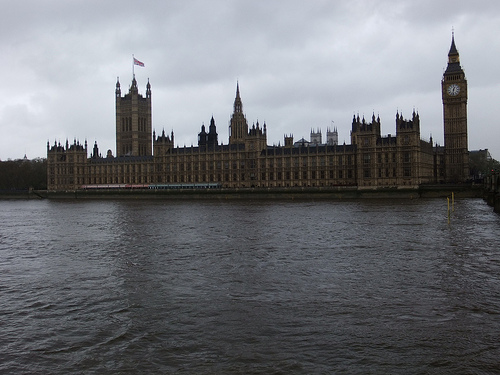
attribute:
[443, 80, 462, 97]
clock —  round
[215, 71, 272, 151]
tower — pointy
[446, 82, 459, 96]
clock — white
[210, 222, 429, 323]
water — dark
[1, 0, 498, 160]
clouds — grey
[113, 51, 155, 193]
tower flag — tall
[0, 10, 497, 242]
day — grey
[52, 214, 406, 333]
water —  brown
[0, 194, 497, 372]
water — calm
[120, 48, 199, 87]
flag — waiving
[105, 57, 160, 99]
flag — flying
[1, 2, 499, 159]
sky —  dark, gloomy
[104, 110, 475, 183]
photo — tourist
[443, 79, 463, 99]
clock — white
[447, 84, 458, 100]
numbers — black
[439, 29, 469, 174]
tower — clock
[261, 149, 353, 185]
windows — many